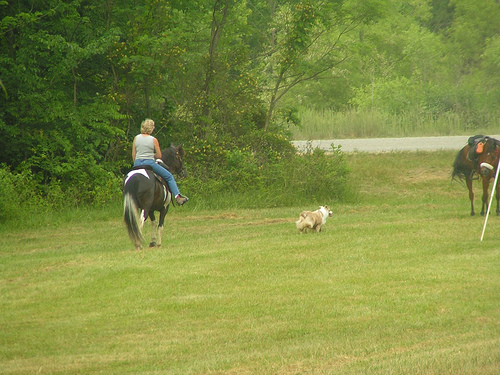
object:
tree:
[254, 0, 348, 173]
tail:
[450, 147, 472, 188]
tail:
[123, 184, 147, 249]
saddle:
[467, 134, 497, 163]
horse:
[450, 134, 500, 217]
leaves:
[1, 0, 313, 205]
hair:
[140, 118, 155, 134]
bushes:
[210, 105, 287, 210]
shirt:
[133, 133, 155, 161]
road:
[284, 127, 496, 158]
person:
[131, 118, 188, 205]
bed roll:
[474, 135, 490, 154]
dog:
[295, 204, 333, 233]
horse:
[121, 143, 186, 251]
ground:
[0, 209, 498, 373]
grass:
[0, 150, 499, 374]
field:
[0, 146, 500, 373]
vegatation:
[12, 142, 364, 232]